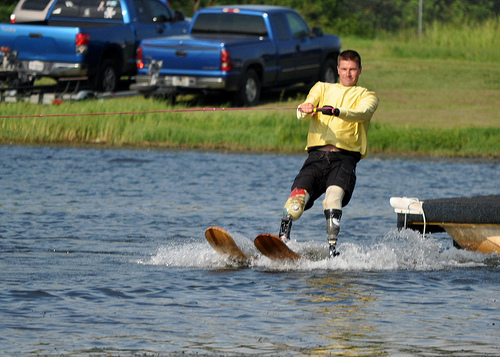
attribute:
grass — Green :
[1, 94, 498, 153]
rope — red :
[0, 90, 340, 112]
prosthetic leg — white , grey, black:
[322, 186, 344, 260]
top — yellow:
[296, 82, 379, 157]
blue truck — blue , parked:
[35, 14, 170, 115]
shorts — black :
[288, 137, 369, 213]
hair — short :
[335, 47, 361, 64]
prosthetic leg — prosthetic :
[322, 178, 342, 261]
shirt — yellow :
[294, 72, 389, 162]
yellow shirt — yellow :
[294, 81, 381, 156]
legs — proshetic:
[260, 185, 347, 236]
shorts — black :
[288, 145, 359, 199]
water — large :
[1, 138, 498, 355]